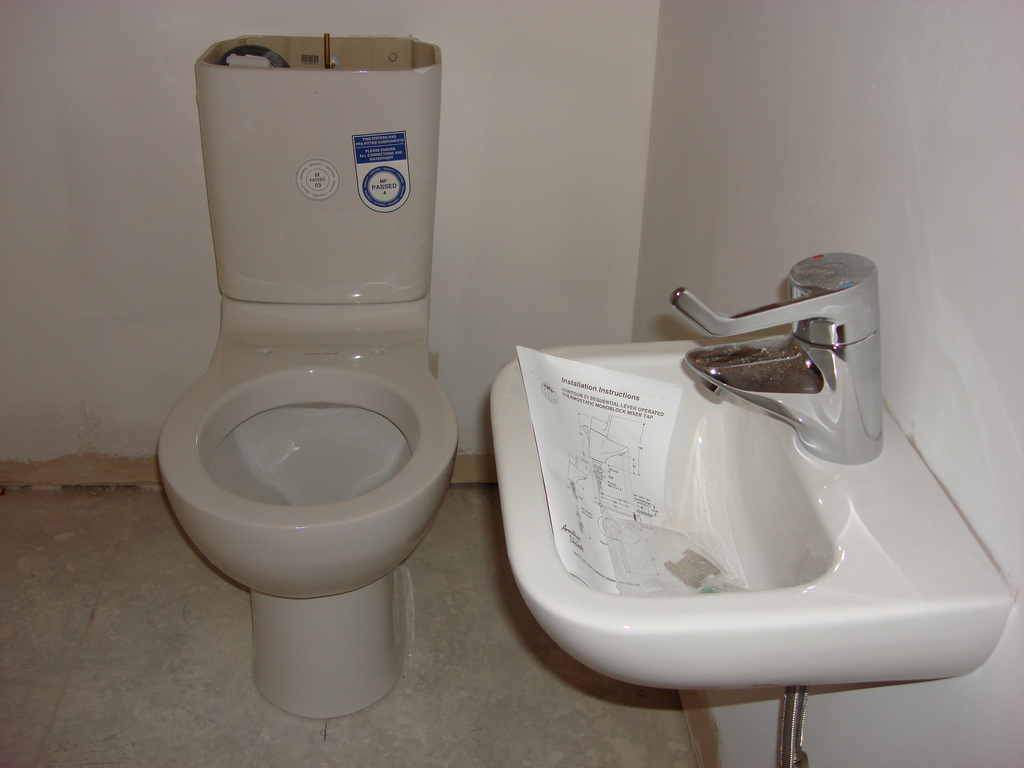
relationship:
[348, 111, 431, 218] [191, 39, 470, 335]
label on tank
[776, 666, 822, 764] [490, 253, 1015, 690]
pipe under sink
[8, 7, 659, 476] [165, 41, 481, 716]
wall on left of toilet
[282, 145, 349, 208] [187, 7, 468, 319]
sticker in center of toilet tank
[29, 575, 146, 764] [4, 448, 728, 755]
line on floor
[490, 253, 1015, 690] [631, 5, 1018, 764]
sink attached to wall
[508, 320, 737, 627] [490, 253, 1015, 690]
instruction book in sink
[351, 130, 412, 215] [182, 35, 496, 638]
label on toilet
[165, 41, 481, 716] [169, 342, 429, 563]
toilet has bowl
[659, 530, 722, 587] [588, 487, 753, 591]
item in cover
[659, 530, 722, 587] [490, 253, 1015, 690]
item in sink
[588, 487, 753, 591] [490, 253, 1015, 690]
cover in sink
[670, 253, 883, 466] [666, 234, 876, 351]
water faucet has handle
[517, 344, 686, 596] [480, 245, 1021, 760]
instruction book inside sink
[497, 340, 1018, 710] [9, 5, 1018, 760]
sink in bathroom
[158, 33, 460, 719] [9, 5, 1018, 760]
toilet in bathroom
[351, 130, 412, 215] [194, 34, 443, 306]
label on tank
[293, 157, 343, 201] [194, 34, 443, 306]
sticker on tank